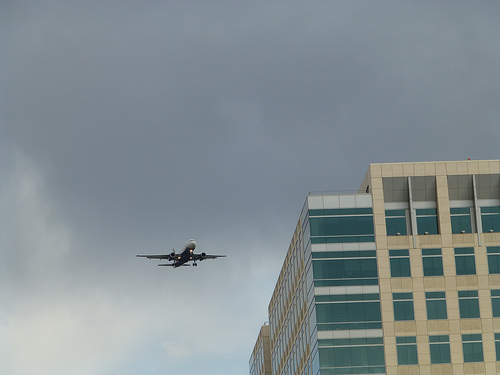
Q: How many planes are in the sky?
A: One.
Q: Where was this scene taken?
A: Ontario.